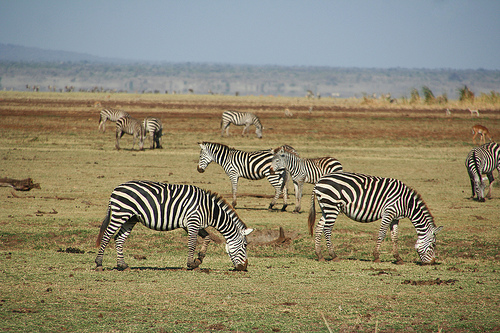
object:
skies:
[1, 0, 498, 70]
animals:
[463, 105, 484, 117]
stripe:
[314, 186, 341, 201]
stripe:
[319, 196, 343, 206]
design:
[321, 172, 362, 213]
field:
[0, 91, 500, 332]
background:
[0, 0, 500, 332]